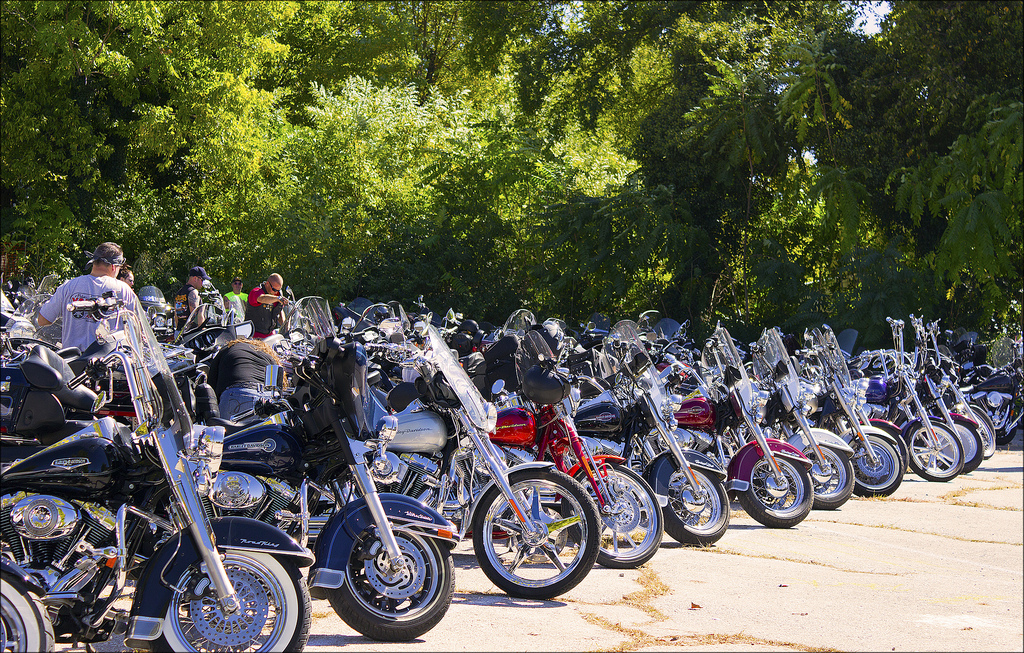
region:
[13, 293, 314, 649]
shiny bike lined in a row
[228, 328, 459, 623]
shiny bike lined in a row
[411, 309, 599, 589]
shiny bike lined in a row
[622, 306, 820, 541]
shiny bike lined in a row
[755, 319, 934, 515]
shiny bike lined in a row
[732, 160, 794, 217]
green leaves in brown tree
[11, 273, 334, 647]
a two wheeled motorcycle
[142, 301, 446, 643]
a two wheeled motorcycle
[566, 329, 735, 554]
a two wheeled motorcycle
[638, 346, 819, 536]
a two wheeled motorcycle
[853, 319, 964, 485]
a two wheeled motorcycle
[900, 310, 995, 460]
a two wheeled motorcycle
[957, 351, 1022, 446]
a two wheeled motorcycle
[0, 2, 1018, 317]
green leaves on trees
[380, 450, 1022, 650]
weeds growing in cracked pavement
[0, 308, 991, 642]
line of parked motorbikes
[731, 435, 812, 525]
red fender over tire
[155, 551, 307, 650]
tire with white wall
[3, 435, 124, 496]
emblem on gas tank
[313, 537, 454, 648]
shadow under bike tire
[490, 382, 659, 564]
bike with red body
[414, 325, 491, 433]
windshield on front of bike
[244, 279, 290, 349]
Man wearing a shirt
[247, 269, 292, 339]
Man is wearing a shirt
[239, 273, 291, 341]
Man wearing a red shirt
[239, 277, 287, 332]
Man is wearing a red shirt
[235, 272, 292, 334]
Man wearing a vest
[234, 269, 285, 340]
Man is wearing a vest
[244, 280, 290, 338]
Man wearing a black vest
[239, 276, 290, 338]
Man is wearing a black vest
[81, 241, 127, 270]
Man wearing a bandana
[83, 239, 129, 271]
Man is wearing a bandana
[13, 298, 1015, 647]
A roll of motorcycles.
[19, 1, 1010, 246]
A group of leafy green trees.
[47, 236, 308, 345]
A group of people looking at motorcycles.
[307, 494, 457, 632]
A front wheel of a motorcycle.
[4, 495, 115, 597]
A motor on a motorcycle.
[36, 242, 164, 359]
A man in a gray shirt.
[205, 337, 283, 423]
A person in a black shirt .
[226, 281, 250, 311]
A person in a green shirt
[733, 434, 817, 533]
A front tire of purple motor cycle.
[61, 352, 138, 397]
A handle bar of a motorcycle.